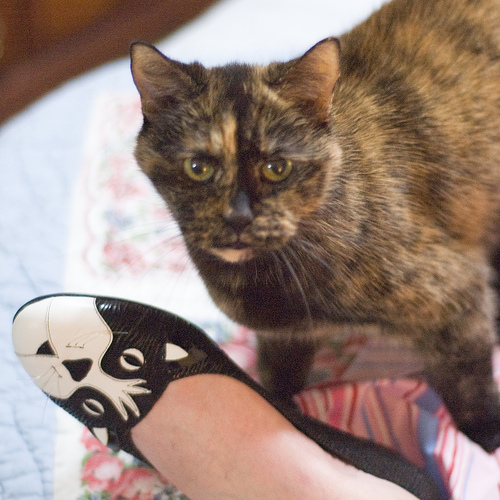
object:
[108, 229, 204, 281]
whiskers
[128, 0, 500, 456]
brown cat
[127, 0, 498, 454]
tan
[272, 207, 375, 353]
whiskers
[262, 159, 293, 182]
eye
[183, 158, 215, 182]
green eye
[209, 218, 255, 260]
mouth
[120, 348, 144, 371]
eye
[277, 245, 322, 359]
whisker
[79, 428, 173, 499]
flowers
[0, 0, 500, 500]
blanket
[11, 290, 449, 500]
woman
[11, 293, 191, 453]
cat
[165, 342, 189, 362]
ear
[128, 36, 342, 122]
ears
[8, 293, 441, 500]
black shoe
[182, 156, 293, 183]
eyes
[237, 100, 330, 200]
fur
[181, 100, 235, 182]
fur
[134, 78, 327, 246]
face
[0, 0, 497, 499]
bed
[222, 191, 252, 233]
nose